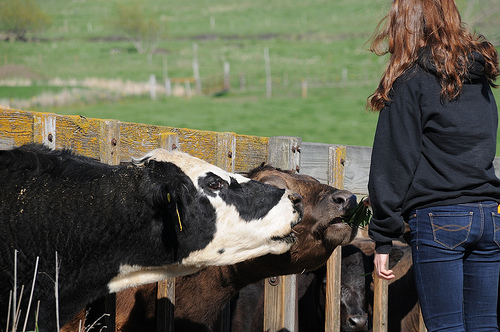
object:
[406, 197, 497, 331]
jeans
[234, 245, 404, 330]
cow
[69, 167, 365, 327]
cow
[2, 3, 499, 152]
grass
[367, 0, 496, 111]
hair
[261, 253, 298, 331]
pole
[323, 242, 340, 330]
pole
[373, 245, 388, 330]
pole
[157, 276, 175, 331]
pole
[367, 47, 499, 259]
sweatshirt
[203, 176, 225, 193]
eye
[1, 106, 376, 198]
fence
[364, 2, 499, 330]
woman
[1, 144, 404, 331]
cows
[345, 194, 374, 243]
plant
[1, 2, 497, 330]
photo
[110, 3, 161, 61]
tree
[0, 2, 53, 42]
tree